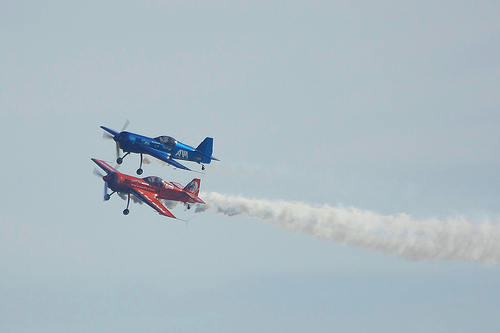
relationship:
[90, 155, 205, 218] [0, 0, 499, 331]
plane in sky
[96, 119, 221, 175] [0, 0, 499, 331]
plane in sky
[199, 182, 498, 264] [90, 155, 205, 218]
smoke coming from plane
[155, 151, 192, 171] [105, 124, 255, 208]
wing on plane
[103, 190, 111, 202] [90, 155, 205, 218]
front wheel on plane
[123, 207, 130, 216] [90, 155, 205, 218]
wheel on plane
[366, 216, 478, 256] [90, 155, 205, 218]
smoke from plane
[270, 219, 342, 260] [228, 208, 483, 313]
section of sky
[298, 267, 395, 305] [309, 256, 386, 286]
section of sky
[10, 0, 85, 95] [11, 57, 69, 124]
section of sky